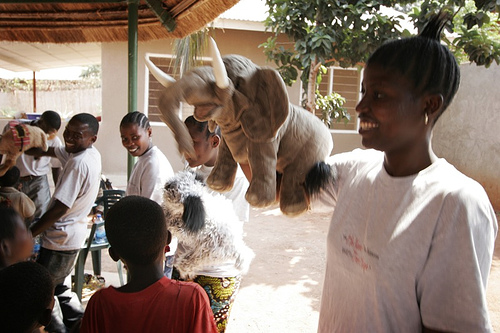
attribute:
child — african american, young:
[78, 194, 217, 329]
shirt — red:
[77, 276, 219, 331]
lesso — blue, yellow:
[200, 262, 246, 315]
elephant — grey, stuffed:
[138, 45, 335, 208]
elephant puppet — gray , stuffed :
[141, 34, 337, 210]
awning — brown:
[1, 0, 243, 40]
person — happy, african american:
[234, 9, 472, 328]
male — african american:
[30, 108, 107, 278]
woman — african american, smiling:
[311, 6, 498, 331]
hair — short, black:
[73, 110, 109, 138]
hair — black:
[362, 5, 464, 100]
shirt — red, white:
[306, 145, 496, 331]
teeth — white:
[359, 119, 399, 135]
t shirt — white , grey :
[297, 141, 498, 331]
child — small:
[321, 50, 487, 326]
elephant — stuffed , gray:
[69, 11, 394, 228]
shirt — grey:
[321, 133, 497, 313]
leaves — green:
[294, 14, 329, 64]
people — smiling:
[68, 101, 158, 167]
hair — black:
[365, 17, 459, 100]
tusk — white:
[200, 30, 234, 94]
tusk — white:
[137, 47, 180, 89]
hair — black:
[360, 3, 464, 132]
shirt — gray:
[39, 143, 104, 251]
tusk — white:
[202, 26, 232, 91]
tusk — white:
[141, 53, 171, 83]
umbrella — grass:
[6, 6, 236, 69]